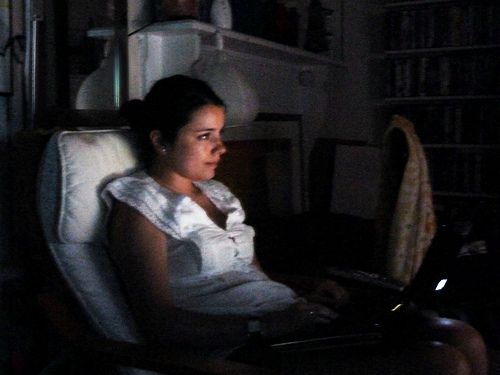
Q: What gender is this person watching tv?
A: Female.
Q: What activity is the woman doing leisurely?
A: Watching tv.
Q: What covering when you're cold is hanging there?
A: Blanket.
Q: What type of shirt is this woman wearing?
A: Sleeveless.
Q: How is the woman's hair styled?
A: Ponytail.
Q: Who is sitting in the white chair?
A: Woman in white blouse.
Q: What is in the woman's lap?
A: Laptop computer.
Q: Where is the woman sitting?
A: In a chair.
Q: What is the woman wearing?
A: White blouse.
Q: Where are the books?
A: Bookcase.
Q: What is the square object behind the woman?
A: Fireplace.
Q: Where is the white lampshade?
A: Behind woman's head.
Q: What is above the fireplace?
A: Mantelpiece.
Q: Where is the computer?
A: Woman's lap.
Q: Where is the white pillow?
A: In chair behind woman.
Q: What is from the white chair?
A: The white pillow.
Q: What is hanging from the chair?
A: The sheet.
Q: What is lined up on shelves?
A: The books.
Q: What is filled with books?
A: The shelves.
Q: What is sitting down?
A: The woman.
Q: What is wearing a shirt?
A: The woman.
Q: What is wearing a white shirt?
A: The woman.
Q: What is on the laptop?
A: The woman.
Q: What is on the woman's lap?
A: The laptop.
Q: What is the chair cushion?
A: White.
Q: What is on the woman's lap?
A: Laptop.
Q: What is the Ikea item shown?
A: Chair.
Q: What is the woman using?
A: Laptop.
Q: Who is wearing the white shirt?
A: The woman.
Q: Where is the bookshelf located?
A: The wall.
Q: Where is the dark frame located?
A: The wall.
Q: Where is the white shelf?
A: Against the wall.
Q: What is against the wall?
A: Fireplace.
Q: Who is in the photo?
A: Girl.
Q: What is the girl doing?
A: Typing.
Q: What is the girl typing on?
A: Laptop.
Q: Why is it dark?
A: Lights out.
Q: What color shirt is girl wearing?
A: White.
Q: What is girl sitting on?
A: Chair.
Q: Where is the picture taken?
A: In a dark room.